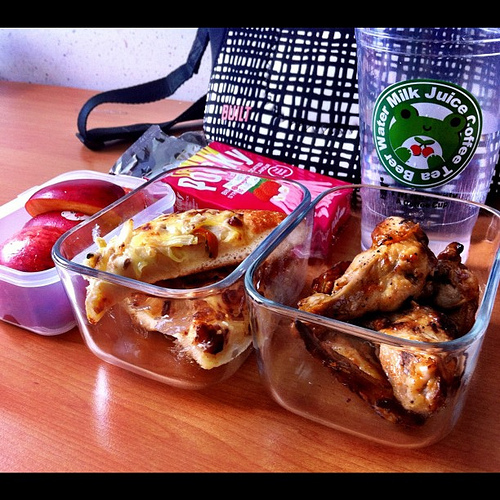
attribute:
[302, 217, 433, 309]
wing — chicken, cooked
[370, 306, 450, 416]
wing — chicken, cooked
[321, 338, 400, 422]
wing — chicken, cooked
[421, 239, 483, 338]
wing — chicken, cooked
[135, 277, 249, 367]
pizza slice — glass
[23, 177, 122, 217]
apple slice — red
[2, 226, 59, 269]
apple slice — red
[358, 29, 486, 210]
tumbler glass — plastic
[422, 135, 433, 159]
small fruit — one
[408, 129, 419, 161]
small fruit — one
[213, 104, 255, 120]
"built" — word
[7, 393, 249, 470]
countertop — wooden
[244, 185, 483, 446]
container — glass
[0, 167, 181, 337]
container — plastic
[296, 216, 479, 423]
cooked food — well cooked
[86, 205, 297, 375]
cooked food — well cooked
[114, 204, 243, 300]
food — well seasoned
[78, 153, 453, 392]
containers — flavored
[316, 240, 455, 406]
chicken — tasty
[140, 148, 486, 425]
containers — good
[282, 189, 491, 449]
container — glass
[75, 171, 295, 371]
container — glass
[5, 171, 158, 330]
container — plastic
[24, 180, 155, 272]
apple — sliced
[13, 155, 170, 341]
container — plastic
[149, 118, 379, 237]
box — red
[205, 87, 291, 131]
letters — pink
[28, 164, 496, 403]
containers — small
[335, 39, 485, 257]
cup — plastic, drinking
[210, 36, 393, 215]
bag — white, black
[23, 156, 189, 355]
container — small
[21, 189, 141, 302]
apple — sliced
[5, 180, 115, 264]
apple — sliced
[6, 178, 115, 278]
apple — brown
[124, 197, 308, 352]
pizza — small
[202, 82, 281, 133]
letting — pink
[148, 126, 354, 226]
box — red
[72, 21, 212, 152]
strap — black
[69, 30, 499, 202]
bag — black, white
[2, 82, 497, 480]
table — brown, wooden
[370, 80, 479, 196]
emblem — green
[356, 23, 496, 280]
cup — plastic, empty